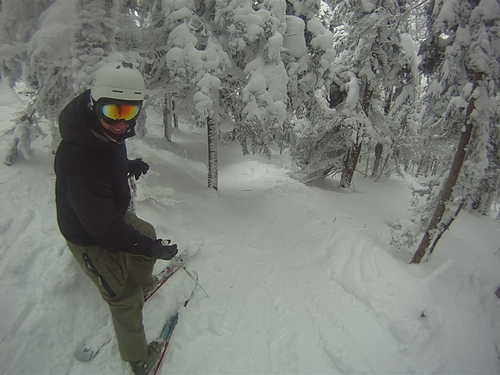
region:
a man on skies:
[34, 51, 296, 371]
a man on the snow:
[37, 41, 326, 373]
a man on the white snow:
[53, 48, 303, 371]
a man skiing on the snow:
[65, 16, 300, 373]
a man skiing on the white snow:
[33, 48, 288, 352]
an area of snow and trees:
[84, 14, 497, 314]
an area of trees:
[23, 1, 497, 331]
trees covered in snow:
[22, 1, 492, 343]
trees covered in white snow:
[72, 21, 464, 303]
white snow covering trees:
[52, 16, 497, 228]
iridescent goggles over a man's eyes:
[96, 101, 141, 123]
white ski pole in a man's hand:
[157, 239, 218, 300]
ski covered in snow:
[139, 271, 213, 374]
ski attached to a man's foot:
[129, 269, 209, 374]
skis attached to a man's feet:
[72, 236, 205, 373]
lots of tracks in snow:
[206, 217, 384, 372]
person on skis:
[53, 59, 213, 374]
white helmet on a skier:
[89, 59, 148, 101]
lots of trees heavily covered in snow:
[142, 1, 499, 263]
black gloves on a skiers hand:
[150, 238, 180, 260]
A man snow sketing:
[64, 76, 195, 364]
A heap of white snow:
[197, 209, 292, 352]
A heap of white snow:
[0, 237, 67, 369]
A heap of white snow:
[318, 256, 435, 339]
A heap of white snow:
[238, 168, 320, 239]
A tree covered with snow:
[173, 21, 228, 206]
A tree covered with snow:
[243, 15, 305, 200]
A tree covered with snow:
[332, 18, 384, 217]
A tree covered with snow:
[444, 20, 487, 269]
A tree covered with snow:
[19, 21, 66, 136]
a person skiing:
[50, 56, 197, 370]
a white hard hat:
[95, 61, 142, 116]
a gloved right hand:
[157, 235, 180, 272]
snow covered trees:
[174, 0, 406, 192]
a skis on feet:
[86, 248, 200, 359]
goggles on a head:
[103, 100, 139, 122]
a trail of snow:
[223, 137, 463, 337]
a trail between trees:
[196, 98, 491, 318]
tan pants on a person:
[56, 213, 166, 365]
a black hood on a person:
[50, 96, 139, 258]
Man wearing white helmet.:
[86, 58, 151, 103]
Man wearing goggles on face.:
[98, 89, 193, 143]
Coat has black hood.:
[60, 98, 117, 152]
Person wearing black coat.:
[49, 143, 137, 223]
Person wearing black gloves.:
[149, 235, 196, 272]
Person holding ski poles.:
[125, 90, 227, 297]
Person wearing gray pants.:
[46, 203, 151, 344]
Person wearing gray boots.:
[126, 324, 157, 369]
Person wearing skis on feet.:
[103, 242, 197, 373]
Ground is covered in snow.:
[179, 167, 313, 297]